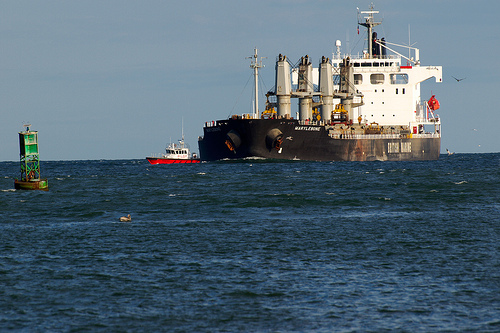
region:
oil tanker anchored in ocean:
[198, 23, 465, 190]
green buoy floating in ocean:
[16, 113, 70, 199]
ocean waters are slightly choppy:
[0, 136, 499, 330]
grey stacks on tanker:
[265, 48, 362, 139]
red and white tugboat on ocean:
[121, 113, 213, 172]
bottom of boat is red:
[149, 157, 205, 167]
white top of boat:
[161, 138, 201, 165]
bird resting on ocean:
[116, 210, 142, 225]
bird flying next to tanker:
[451, 68, 476, 89]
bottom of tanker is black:
[204, 114, 444, 164]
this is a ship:
[209, 57, 439, 168]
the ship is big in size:
[199, 50, 446, 156]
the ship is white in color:
[363, 78, 412, 124]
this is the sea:
[200, 197, 299, 331]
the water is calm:
[266, 218, 393, 319]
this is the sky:
[55, 13, 167, 96]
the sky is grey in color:
[48, 10, 175, 108]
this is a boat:
[9, 115, 48, 192]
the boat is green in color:
[8, 122, 44, 191]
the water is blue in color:
[280, 199, 416, 329]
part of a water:
[262, 239, 291, 271]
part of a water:
[327, 216, 359, 263]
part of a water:
[333, 288, 353, 323]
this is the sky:
[21, 5, 79, 56]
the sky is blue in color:
[26, 18, 101, 77]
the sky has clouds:
[66, 47, 136, 111]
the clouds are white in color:
[96, 9, 178, 69]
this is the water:
[186, 178, 336, 307]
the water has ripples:
[205, 206, 313, 313]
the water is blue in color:
[140, 220, 200, 305]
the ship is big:
[168, 34, 422, 161]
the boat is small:
[142, 139, 199, 164]